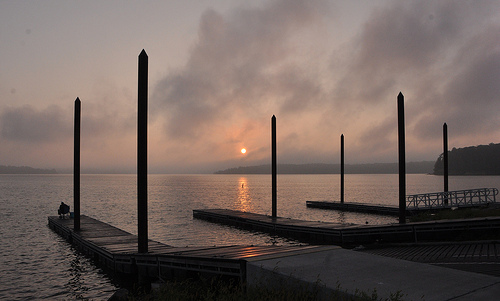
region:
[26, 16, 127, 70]
this is the sky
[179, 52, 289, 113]
this is the cloud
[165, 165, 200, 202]
this is a water body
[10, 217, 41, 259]
the water is calm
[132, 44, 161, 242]
this is a pole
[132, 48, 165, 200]
the pole is black in color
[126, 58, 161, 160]
the pole is long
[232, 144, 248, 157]
this is the sun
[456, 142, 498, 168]
this is the hill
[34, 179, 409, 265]
three wood boat docks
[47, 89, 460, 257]
six wood post on boat docks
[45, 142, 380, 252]
a large body of water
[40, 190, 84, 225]
a person sitting in a chair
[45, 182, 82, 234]
a person sitting on a boat dock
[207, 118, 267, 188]
the sun setting in the sky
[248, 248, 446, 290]
a concrete walkway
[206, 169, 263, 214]
reflection of the sun on the water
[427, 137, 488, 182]
several trees next to the water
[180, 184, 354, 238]
a boat dock on the water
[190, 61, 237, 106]
white clouds in blue sky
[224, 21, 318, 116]
white clouds in blue sky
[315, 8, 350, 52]
white clouds in blue sky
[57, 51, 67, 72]
white clouds in blue sky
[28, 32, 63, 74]
white clouds in blue sky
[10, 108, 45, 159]
white clouds in blue sky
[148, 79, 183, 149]
white clouds in blue sky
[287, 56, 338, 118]
white clouds in blue sky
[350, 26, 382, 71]
white clouds in blue sky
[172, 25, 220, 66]
white clouds in blue sky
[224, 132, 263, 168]
the sun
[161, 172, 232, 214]
the water is calm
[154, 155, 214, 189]
the water is calm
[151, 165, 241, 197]
the water is calm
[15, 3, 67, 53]
white clouds in blue sky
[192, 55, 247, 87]
white clouds in blue sky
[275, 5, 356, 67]
white clouds in blue sky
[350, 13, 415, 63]
white clouds in blue sky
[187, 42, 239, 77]
white clouds in blue sky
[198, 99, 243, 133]
white clouds in blue sky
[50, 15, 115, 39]
white clouds in blue sky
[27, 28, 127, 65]
white clouds in blue sky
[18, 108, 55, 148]
white clouds in blue sky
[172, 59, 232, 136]
white clouds in blue sky